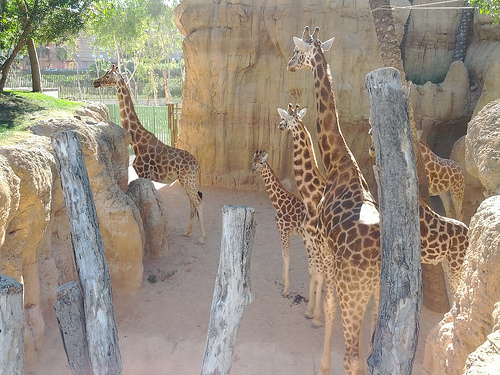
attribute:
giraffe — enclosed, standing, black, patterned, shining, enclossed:
[287, 26, 379, 374]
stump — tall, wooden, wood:
[357, 66, 423, 375]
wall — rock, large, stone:
[176, 2, 497, 202]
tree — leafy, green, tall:
[3, 2, 99, 96]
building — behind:
[21, 42, 79, 72]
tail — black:
[197, 162, 205, 203]